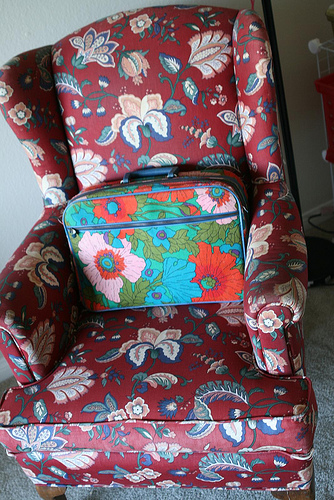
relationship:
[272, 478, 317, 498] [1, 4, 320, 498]
leg of chair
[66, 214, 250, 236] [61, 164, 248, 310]
zipper on briefcase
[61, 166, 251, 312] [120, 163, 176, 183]
bag has handle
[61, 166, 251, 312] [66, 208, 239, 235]
bag has zipper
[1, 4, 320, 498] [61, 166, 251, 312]
chair with bag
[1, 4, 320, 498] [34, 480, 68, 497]
chair has left leg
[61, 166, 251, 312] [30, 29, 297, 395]
bag on chair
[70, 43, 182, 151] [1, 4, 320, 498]
flower design on chair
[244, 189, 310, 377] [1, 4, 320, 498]
arm rest on chair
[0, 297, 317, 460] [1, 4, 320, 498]
cushion on top of chair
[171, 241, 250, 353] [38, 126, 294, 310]
flower on suitcase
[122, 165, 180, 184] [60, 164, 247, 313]
handle on suitcase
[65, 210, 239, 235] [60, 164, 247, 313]
zipper on front of suitcase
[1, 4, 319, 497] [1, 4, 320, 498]
flower on a chair